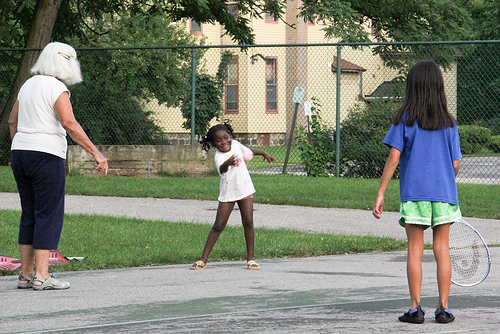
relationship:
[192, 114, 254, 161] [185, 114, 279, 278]
head of girl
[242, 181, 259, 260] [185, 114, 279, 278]
leg of girl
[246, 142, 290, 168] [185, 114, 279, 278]
arm of girl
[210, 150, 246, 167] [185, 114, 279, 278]
hand of girl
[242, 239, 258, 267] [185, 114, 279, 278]
foot of girl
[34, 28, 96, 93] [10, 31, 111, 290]
head of woman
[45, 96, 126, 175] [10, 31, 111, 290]
arm of woman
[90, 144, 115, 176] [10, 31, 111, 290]
hand of woman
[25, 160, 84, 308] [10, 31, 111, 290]
leg of woman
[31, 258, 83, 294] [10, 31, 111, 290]
foot of woman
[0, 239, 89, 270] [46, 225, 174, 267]
equipment on grass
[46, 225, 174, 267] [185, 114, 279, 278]
grass behind girl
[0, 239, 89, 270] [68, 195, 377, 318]
equipment on ground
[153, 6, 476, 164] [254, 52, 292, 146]
building has window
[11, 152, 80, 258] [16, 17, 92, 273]
pants on lady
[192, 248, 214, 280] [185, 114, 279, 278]
sandals with girl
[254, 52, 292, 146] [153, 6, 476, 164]
window of building